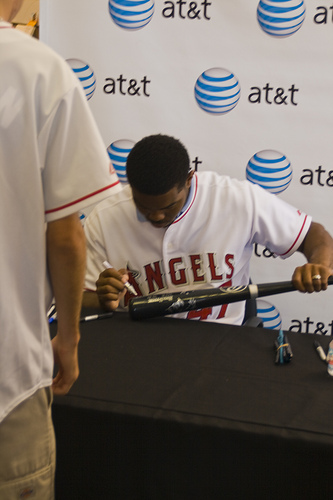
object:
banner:
[37, 0, 332, 338]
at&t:
[103, 1, 218, 34]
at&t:
[191, 67, 303, 118]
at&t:
[63, 58, 151, 101]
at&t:
[244, 147, 332, 198]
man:
[1, 14, 122, 499]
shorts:
[0, 386, 58, 498]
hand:
[49, 332, 86, 398]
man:
[78, 133, 332, 329]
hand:
[286, 261, 332, 294]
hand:
[94, 263, 134, 314]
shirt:
[1, 19, 122, 426]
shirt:
[82, 170, 312, 326]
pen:
[310, 336, 328, 363]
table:
[48, 296, 333, 498]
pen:
[75, 309, 115, 324]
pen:
[48, 310, 62, 328]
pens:
[270, 328, 297, 366]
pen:
[100, 254, 137, 298]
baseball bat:
[126, 269, 333, 323]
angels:
[120, 250, 233, 310]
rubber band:
[272, 339, 292, 348]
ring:
[310, 272, 324, 282]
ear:
[185, 166, 195, 190]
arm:
[43, 54, 92, 400]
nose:
[147, 207, 168, 225]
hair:
[126, 132, 190, 196]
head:
[125, 131, 195, 230]